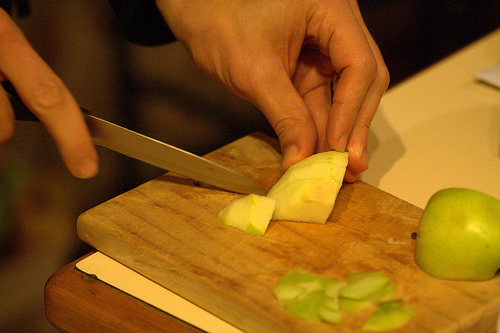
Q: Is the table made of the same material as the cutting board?
A: Yes, both the table and the cutting board are made of wood.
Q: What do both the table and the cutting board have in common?
A: The material, both the table and the cutting board are wooden.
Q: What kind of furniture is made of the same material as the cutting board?
A: The table is made of the same material as the cutting board.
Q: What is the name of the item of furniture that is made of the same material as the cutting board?
A: The piece of furniture is a table.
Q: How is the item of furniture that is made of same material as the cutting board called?
A: The piece of furniture is a table.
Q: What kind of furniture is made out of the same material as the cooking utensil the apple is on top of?
A: The table is made of the same material as the cutting board.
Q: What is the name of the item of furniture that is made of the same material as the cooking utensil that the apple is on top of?
A: The piece of furniture is a table.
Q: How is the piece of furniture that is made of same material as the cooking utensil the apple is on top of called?
A: The piece of furniture is a table.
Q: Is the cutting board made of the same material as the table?
A: Yes, both the cutting board and the table are made of wood.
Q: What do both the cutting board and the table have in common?
A: The material, both the cutting board and the table are wooden.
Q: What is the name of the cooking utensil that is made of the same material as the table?
A: The cooking utensil is a cutting board.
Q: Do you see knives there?
A: Yes, there is a knife.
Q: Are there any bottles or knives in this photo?
A: Yes, there is a knife.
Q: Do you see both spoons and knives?
A: No, there is a knife but no spoons.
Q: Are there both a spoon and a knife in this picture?
A: No, there is a knife but no spoons.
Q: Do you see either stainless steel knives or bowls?
A: Yes, there is a stainless steel knife.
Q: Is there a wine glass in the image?
A: No, there are no wine glasses.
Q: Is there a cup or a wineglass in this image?
A: No, there are no wine glasses or cups.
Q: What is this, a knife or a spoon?
A: This is a knife.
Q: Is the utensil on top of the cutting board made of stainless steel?
A: Yes, the knife is made of stainless steel.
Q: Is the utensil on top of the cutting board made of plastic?
A: No, the knife is made of stainless steel.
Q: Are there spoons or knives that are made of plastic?
A: No, there is a knife but it is made of stainless steel.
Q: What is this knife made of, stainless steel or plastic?
A: The knife is made of stainless steel.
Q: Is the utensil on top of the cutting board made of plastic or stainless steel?
A: The knife is made of stainless steel.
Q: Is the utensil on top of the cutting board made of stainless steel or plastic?
A: The knife is made of stainless steel.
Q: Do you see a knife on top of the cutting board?
A: Yes, there is a knife on top of the cutting board.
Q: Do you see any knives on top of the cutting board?
A: Yes, there is a knife on top of the cutting board.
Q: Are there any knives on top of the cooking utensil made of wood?
A: Yes, there is a knife on top of the cutting board.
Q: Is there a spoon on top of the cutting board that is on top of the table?
A: No, there is a knife on top of the cutting board.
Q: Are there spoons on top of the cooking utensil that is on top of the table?
A: No, there is a knife on top of the cutting board.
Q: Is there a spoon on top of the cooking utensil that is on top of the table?
A: No, there is a knife on top of the cutting board.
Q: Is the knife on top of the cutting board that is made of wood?
A: Yes, the knife is on top of the cutting board.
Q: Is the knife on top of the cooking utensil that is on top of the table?
A: Yes, the knife is on top of the cutting board.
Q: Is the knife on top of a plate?
A: No, the knife is on top of the cutting board.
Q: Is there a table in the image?
A: Yes, there is a table.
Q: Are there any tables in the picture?
A: Yes, there is a table.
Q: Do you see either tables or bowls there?
A: Yes, there is a table.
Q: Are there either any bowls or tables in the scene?
A: Yes, there is a table.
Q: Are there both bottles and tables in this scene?
A: No, there is a table but no bottles.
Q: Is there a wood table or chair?
A: Yes, there is a wood table.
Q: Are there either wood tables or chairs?
A: Yes, there is a wood table.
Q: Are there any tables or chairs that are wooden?
A: Yes, the table is wooden.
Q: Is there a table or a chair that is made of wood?
A: Yes, the table is made of wood.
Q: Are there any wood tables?
A: Yes, there is a wood table.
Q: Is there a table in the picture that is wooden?
A: Yes, there is a table that is wooden.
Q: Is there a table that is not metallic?
A: Yes, there is a wooden table.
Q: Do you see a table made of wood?
A: Yes, there is a table that is made of wood.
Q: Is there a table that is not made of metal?
A: Yes, there is a table that is made of wood.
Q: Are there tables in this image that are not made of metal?
A: Yes, there is a table that is made of wood.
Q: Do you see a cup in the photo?
A: No, there are no cups.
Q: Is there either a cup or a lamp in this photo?
A: No, there are no cups or lamps.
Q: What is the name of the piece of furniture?
A: The piece of furniture is a table.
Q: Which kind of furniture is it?
A: The piece of furniture is a table.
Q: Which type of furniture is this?
A: This is a table.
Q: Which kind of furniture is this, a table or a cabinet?
A: This is a table.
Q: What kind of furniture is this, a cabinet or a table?
A: This is a table.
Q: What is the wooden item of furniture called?
A: The piece of furniture is a table.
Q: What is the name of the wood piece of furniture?
A: The piece of furniture is a table.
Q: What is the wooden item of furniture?
A: The piece of furniture is a table.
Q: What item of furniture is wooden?
A: The piece of furniture is a table.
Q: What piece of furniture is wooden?
A: The piece of furniture is a table.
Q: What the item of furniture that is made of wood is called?
A: The piece of furniture is a table.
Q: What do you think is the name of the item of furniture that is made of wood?
A: The piece of furniture is a table.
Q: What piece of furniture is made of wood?
A: The piece of furniture is a table.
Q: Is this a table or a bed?
A: This is a table.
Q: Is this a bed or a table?
A: This is a table.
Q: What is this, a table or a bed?
A: This is a table.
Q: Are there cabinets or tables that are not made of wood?
A: No, there is a table but it is made of wood.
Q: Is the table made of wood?
A: Yes, the table is made of wood.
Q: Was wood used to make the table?
A: Yes, the table is made of wood.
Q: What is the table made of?
A: The table is made of wood.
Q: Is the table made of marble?
A: No, the table is made of wood.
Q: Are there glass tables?
A: No, there is a table but it is made of wood.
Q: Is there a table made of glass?
A: No, there is a table but it is made of wood.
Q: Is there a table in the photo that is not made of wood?
A: No, there is a table but it is made of wood.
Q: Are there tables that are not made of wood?
A: No, there is a table but it is made of wood.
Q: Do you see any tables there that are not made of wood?
A: No, there is a table but it is made of wood.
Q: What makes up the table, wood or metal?
A: The table is made of wood.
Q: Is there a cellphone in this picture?
A: No, there are no cell phones.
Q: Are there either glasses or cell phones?
A: No, there are no cell phones or glasses.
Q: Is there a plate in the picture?
A: No, there are no plates.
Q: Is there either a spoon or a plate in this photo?
A: No, there are no plates or spoons.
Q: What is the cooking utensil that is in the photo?
A: The cooking utensil is a cutting board.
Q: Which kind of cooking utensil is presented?
A: The cooking utensil is a cutting board.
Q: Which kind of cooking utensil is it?
A: The cooking utensil is a cutting board.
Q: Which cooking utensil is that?
A: This is a cutting board.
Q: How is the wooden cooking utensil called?
A: The cooking utensil is a cutting board.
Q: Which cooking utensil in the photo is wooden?
A: The cooking utensil is a cutting board.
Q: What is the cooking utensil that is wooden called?
A: The cooking utensil is a cutting board.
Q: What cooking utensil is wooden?
A: The cooking utensil is a cutting board.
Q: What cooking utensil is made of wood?
A: The cooking utensil is a cutting board.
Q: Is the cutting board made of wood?
A: Yes, the cutting board is made of wood.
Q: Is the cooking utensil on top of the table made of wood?
A: Yes, the cutting board is made of wood.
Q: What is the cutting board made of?
A: The cutting board is made of wood.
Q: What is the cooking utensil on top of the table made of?
A: The cutting board is made of wood.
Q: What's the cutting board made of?
A: The cutting board is made of wood.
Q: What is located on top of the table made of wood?
A: The cutting board is on top of the table.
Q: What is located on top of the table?
A: The cutting board is on top of the table.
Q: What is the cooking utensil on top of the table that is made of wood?
A: The cooking utensil is a cutting board.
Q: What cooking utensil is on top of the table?
A: The cooking utensil is a cutting board.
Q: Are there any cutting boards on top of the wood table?
A: Yes, there is a cutting board on top of the table.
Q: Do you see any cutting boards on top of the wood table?
A: Yes, there is a cutting board on top of the table.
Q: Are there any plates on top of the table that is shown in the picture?
A: No, there is a cutting board on top of the table.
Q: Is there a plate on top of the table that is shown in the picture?
A: No, there is a cutting board on top of the table.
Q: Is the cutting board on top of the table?
A: Yes, the cutting board is on top of the table.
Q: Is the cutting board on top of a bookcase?
A: No, the cutting board is on top of the table.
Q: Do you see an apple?
A: Yes, there is an apple.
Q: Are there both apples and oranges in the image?
A: No, there is an apple but no oranges.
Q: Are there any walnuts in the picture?
A: No, there are no walnuts.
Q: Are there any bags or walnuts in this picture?
A: No, there are no walnuts or bags.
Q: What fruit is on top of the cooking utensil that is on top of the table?
A: The fruit is an apple.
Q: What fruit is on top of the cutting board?
A: The fruit is an apple.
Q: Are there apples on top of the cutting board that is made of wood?
A: Yes, there is an apple on top of the cutting board.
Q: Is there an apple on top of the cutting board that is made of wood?
A: Yes, there is an apple on top of the cutting board.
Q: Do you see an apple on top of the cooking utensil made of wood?
A: Yes, there is an apple on top of the cutting board.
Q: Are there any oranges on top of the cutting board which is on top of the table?
A: No, there is an apple on top of the cutting board.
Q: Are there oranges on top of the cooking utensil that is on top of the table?
A: No, there is an apple on top of the cutting board.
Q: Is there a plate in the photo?
A: No, there are no plates.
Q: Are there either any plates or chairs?
A: No, there are no plates or chairs.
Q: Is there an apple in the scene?
A: Yes, there is an apple.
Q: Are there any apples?
A: Yes, there is an apple.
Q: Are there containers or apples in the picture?
A: Yes, there is an apple.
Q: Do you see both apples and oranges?
A: No, there is an apple but no oranges.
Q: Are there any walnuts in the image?
A: No, there are no walnuts.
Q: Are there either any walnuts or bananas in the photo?
A: No, there are no walnuts or bananas.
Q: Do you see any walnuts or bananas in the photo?
A: No, there are no walnuts or bananas.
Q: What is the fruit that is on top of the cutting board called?
A: The fruit is an apple.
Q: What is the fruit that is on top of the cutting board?
A: The fruit is an apple.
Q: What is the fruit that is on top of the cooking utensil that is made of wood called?
A: The fruit is an apple.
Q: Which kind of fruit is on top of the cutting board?
A: The fruit is an apple.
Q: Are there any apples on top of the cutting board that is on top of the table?
A: Yes, there is an apple on top of the cutting board.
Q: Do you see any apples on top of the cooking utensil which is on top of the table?
A: Yes, there is an apple on top of the cutting board.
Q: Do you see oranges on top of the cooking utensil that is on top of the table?
A: No, there is an apple on top of the cutting board.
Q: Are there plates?
A: No, there are no plates.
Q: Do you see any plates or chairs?
A: No, there are no plates or chairs.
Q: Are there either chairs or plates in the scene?
A: No, there are no plates or chairs.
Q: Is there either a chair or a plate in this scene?
A: No, there are no plates or chairs.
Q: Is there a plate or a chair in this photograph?
A: No, there are no plates or chairs.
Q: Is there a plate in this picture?
A: No, there are no plates.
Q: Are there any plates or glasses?
A: No, there are no plates or glasses.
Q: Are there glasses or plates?
A: No, there are no plates or glasses.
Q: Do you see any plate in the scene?
A: No, there are no plates.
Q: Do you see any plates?
A: No, there are no plates.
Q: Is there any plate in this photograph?
A: No, there are no plates.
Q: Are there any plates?
A: No, there are no plates.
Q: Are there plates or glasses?
A: No, there are no plates or glasses.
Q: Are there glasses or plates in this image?
A: No, there are no plates or glasses.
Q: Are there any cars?
A: No, there are no cars.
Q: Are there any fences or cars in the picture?
A: No, there are no cars or fences.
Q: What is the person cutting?
A: The person is cutting the apple.